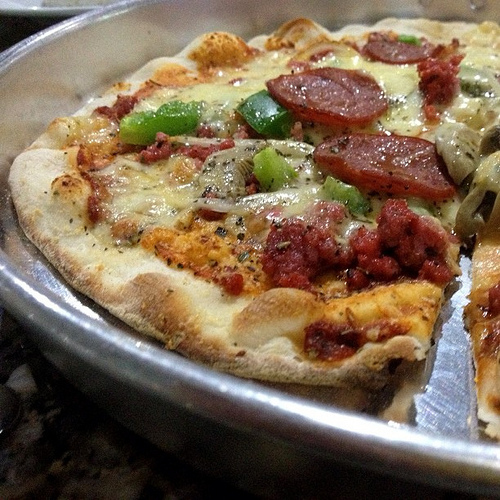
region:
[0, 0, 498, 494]
THE PAN IS SILVER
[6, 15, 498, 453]
THIS IS PIZZA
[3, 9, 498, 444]
THE PIZZA IS ON THE PAN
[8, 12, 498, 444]
THE PIZZA IS SLICED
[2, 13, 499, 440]
THE PIZZA HAS A CRUST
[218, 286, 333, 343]
THE CRUSH HAS A BUBBLE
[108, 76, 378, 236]
THE PIZZA HAS PEPPERS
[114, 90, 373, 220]
THE PEPPERS ARE GREEN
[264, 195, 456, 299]
THE PIZZA HAS SAUSAGE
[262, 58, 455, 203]
THE PIZZA HAS PEPPERONIS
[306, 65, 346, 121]
pepperoni on the pizza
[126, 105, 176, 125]
green pepper on the pizza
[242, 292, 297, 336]
bubble in the crust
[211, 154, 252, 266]
seasoning on the pizza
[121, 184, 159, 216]
cheese on the pizza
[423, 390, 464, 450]
pizza has been cut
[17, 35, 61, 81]
pizza is on a metal pan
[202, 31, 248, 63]
burnt on the crust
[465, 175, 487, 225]
mushroom on the pizza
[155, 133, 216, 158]
tomato sauce on the pizza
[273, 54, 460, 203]
The slices of pepperoni/ham on the pizza.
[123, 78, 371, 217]
The chunks of green peppers.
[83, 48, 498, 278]
The melted cheese on the pizza.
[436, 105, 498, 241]
The pieces of mushroom on the pizza.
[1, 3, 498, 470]
The silver pan the pizza is in.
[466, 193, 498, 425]
The slice of pizza not attached to the pie on the right.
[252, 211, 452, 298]
The red sauce on the pizza.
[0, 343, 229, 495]
The counter the pizza pan is on.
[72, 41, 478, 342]
The black specks on the pizza.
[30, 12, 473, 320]
The crust of the pizza.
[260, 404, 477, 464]
round sliver edge of pizza pan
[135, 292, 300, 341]
pizza crust is brown and bubbly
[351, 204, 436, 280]
tomato sauce is chunky and red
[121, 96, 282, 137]
chopped green peppers on pizza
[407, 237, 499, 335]
pizza is cut into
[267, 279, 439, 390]
pizza crust is thin crust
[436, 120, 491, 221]
slices of mushrooms on top of pizza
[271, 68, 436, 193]
pepperoni slices are big and red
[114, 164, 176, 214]
cheese on pizza is yellow and shiny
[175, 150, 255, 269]
seasoning as a topping on pizza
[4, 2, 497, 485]
pizza on a metal cooking tray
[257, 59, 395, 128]
cooked pepperoni on a pizza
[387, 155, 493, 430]
pizza has been cut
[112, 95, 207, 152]
green bell pepper on a pizza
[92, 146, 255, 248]
melted cheese on a pizza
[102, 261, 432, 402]
crusty edge of a pizza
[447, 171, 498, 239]
olive on a pizza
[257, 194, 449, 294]
cooked tomato on a pizza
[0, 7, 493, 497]
pizza dish is circular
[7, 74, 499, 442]
pizza is round